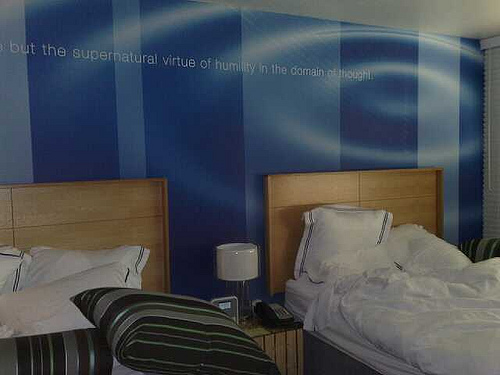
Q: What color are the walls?
A: Blue.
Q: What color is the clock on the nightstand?
A: White and gray.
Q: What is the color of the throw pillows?
A: Black.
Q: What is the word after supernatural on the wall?
A: Virtue.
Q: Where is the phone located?
A: Nightstand.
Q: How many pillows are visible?
A: Eight.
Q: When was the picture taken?
A: Daytime.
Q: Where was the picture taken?
A: Hotel room.